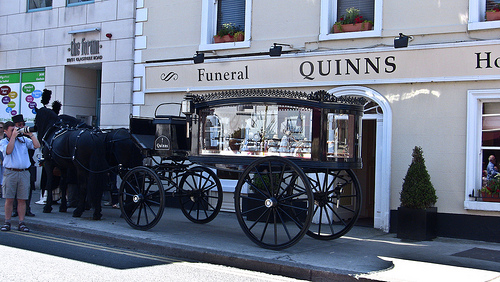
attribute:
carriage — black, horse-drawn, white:
[95, 82, 422, 264]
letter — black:
[362, 49, 382, 80]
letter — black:
[316, 56, 334, 83]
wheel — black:
[227, 155, 323, 262]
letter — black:
[196, 65, 253, 83]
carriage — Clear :
[121, 59, 393, 252]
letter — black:
[332, 57, 343, 79]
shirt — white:
[1, 137, 31, 167]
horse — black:
[34, 108, 135, 218]